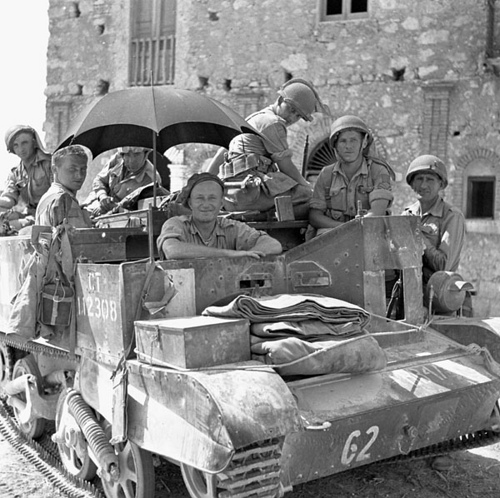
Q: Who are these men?
A: Soldiers.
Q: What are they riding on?
A: A tank.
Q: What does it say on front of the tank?
A: 62.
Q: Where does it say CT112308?
A: The side of the tank.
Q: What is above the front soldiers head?
A: Umbrella.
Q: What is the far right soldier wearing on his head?
A: A helmet.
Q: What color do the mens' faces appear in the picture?
A: Gray.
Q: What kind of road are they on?
A: Dirt.